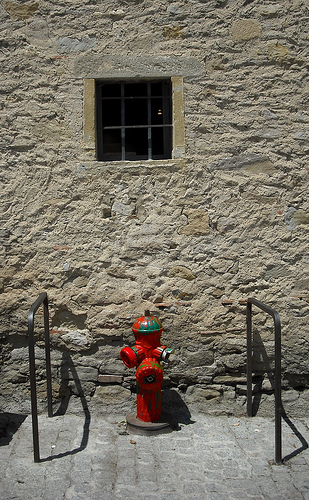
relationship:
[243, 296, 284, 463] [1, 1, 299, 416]
rail standing next to wall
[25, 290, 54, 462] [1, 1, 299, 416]
rail standing next to wall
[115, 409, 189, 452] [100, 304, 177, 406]
base of hydrant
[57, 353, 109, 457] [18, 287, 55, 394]
shadow of railing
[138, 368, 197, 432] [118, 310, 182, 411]
shadow of hydrant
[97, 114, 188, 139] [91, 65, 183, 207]
bars on windows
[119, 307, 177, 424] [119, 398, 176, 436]
hydrant on base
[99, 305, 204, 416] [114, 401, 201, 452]
hydrant on base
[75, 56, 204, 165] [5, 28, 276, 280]
window on wall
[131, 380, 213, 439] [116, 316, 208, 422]
shadow of hydrant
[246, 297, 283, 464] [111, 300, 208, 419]
rail by hydrant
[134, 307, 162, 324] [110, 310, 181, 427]
bolt on hydrant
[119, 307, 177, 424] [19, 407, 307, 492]
hydrant on sidewalk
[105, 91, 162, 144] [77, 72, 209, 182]
bars on window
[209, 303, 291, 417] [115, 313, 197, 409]
pole by hydrant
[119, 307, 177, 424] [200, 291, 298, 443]
hydrant by rails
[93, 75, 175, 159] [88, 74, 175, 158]
bars on window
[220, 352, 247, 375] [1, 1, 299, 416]
brick in wall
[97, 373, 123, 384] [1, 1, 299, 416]
brick in wall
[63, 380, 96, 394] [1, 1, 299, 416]
brick in wall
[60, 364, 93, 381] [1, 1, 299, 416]
brick in wall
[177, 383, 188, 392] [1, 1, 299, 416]
brick in wall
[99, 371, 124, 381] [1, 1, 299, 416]
brick in wall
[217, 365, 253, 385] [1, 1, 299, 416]
brick in wall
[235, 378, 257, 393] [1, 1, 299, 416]
brick in wall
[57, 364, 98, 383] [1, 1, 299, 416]
brick in wall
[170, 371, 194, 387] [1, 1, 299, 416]
brick in wall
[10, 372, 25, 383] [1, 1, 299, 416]
brick in wall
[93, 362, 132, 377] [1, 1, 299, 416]
brick in wall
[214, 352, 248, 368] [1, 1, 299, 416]
brick in wall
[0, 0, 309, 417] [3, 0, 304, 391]
wall on side of building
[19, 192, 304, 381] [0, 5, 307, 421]
wall on side of building